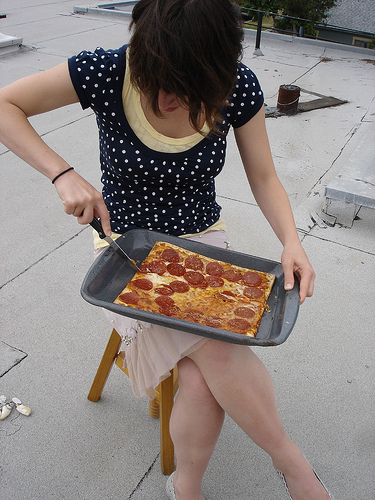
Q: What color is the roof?
A: Gray.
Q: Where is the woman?
A: On roof.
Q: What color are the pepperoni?
A: Red.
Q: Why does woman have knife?
A: To cut.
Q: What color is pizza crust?
A: Tan.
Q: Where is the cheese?
A: On pizza.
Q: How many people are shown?
A: One.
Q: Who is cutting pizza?
A: Woman.